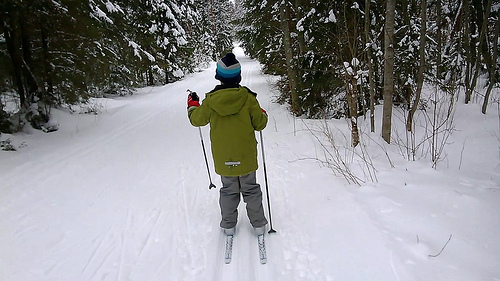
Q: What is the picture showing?
A: It is showing a road.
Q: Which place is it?
A: It is a road.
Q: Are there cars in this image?
A: No, there are no cars.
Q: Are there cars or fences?
A: No, there are no cars or fences.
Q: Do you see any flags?
A: No, there are no flags.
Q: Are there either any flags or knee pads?
A: No, there are no flags or knee pads.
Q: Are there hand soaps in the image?
A: No, there are no hand soaps.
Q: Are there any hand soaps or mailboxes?
A: No, there are no hand soaps or mailboxes.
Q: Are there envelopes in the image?
A: No, there are no envelopes.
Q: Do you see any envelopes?
A: No, there are no envelopes.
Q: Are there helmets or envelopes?
A: No, there are no envelopes or helmets.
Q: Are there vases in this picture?
A: No, there are no vases.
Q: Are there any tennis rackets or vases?
A: No, there are no vases or tennis rackets.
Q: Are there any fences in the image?
A: No, there are no fences.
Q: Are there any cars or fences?
A: No, there are no fences or cars.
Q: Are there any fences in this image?
A: No, there are no fences.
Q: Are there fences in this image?
A: No, there are no fences.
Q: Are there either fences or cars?
A: No, there are no fences or cars.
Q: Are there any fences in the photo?
A: No, there are no fences.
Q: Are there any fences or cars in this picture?
A: No, there are no fences or cars.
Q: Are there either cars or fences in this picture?
A: No, there are no fences or cars.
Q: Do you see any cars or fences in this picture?
A: No, there are no fences or cars.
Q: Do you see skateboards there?
A: No, there are no skateboards.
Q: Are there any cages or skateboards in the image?
A: No, there are no skateboards or cages.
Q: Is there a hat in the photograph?
A: Yes, there is a hat.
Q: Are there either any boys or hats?
A: Yes, there is a hat.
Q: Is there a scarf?
A: No, there are no scarves.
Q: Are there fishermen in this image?
A: No, there are no fishermen.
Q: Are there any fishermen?
A: No, there are no fishermen.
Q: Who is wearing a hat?
A: The boy is wearing a hat.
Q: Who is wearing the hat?
A: The boy is wearing a hat.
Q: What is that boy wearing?
A: The boy is wearing a hat.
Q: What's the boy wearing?
A: The boy is wearing a hat.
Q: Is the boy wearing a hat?
A: Yes, the boy is wearing a hat.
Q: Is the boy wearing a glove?
A: No, the boy is wearing a hat.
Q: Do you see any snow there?
A: Yes, there is snow.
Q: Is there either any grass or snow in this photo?
A: Yes, there is snow.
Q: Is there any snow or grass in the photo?
A: Yes, there is snow.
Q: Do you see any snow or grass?
A: Yes, there is snow.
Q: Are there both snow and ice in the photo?
A: No, there is snow but no ice.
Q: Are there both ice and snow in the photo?
A: No, there is snow but no ice.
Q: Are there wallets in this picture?
A: No, there are no wallets.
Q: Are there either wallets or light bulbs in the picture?
A: No, there are no wallets or light bulbs.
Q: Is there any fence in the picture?
A: No, there are no fences.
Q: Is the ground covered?
A: Yes, the ground is covered.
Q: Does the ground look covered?
A: Yes, the ground is covered.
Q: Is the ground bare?
A: No, the ground is covered.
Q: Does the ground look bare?
A: No, the ground is covered.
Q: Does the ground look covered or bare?
A: The ground is covered.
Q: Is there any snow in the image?
A: Yes, there is snow.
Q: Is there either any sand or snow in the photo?
A: Yes, there is snow.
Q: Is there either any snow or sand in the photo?
A: Yes, there is snow.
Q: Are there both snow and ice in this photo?
A: No, there is snow but no ice.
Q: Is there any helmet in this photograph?
A: No, there are no helmets.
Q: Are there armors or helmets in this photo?
A: No, there are no helmets or armors.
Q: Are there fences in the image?
A: No, there are no fences.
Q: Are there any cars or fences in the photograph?
A: No, there are no fences or cars.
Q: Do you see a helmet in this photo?
A: No, there are no helmets.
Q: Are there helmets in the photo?
A: No, there are no helmets.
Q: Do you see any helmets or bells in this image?
A: No, there are no helmets or bells.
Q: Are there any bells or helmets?
A: No, there are no helmets or bells.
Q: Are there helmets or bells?
A: No, there are no helmets or bells.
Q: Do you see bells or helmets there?
A: No, there are no helmets or bells.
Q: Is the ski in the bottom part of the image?
A: Yes, the ski is in the bottom of the image.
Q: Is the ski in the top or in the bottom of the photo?
A: The ski is in the bottom of the image.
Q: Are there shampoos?
A: No, there are no shampoos.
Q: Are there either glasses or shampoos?
A: No, there are no shampoos or glasses.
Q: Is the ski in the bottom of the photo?
A: Yes, the ski is in the bottom of the image.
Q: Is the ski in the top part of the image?
A: No, the ski is in the bottom of the image.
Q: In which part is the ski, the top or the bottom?
A: The ski is in the bottom of the image.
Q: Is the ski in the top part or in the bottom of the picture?
A: The ski is in the bottom of the image.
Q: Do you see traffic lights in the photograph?
A: No, there are no traffic lights.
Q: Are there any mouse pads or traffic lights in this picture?
A: No, there are no traffic lights or mouse pads.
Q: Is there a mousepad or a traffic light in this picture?
A: No, there are no traffic lights or mouse pads.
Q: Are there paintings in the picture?
A: No, there are no paintings.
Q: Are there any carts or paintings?
A: No, there are no paintings or carts.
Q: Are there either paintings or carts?
A: No, there are no paintings or carts.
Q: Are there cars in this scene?
A: No, there are no cars.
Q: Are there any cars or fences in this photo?
A: No, there are no cars or fences.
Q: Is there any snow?
A: Yes, there is snow.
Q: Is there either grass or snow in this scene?
A: Yes, there is snow.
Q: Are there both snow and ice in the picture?
A: No, there is snow but no ice.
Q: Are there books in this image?
A: No, there are no books.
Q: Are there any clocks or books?
A: No, there are no books or clocks.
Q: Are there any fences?
A: No, there are no fences.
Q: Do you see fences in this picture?
A: No, there are no fences.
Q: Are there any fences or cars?
A: No, there are no fences or cars.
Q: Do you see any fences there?
A: No, there are no fences.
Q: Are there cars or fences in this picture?
A: No, there are no fences or cars.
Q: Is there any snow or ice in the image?
A: Yes, there is snow.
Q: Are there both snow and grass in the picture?
A: No, there is snow but no grass.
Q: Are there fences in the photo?
A: No, there are no fences.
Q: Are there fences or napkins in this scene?
A: No, there are no fences or napkins.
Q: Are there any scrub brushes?
A: No, there are no scrub brushes.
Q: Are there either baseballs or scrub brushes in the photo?
A: No, there are no scrub brushes or baseballs.